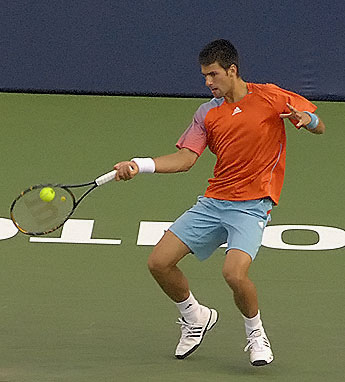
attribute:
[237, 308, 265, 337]
sock — white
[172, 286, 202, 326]
sock — white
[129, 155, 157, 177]
wristband — in the picture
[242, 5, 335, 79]
blue wall — in the picture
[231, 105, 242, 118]
logo — white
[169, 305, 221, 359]
shoes — white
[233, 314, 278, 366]
shoes — white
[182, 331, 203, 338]
lines — black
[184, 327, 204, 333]
lines — black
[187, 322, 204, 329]
lines — black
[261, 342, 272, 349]
lines — black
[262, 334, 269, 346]
lines — black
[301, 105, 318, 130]
sweatband — blue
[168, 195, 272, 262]
shorts — blue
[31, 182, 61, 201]
ball — yellow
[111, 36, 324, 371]
tennis player — in the picture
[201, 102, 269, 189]
t-shirt — orange 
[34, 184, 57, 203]
ball — neon, green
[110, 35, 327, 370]
man — in the picture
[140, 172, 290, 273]
shorts — Blue 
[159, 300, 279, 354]
shoes — in the picture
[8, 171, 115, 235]
racket — black, gold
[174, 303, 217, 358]
shoe — in the picture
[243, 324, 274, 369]
shoe — black , white 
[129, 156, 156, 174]
sweatband — white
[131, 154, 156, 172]
wristband — white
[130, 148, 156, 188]
band — white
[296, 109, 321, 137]
wrist band — light blue